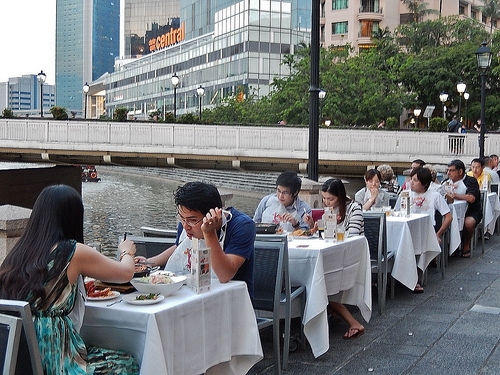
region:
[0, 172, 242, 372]
Man and woman sitting at table eating.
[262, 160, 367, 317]
Man and woman sitting side by side at table.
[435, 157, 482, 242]
Man with napkin under his chin.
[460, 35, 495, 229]
Black ornamental sidewalk light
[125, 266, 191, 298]
White porcelain bowl holding food.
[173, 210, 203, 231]
Eye glasses on man's face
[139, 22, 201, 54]
Large lettered sign on top of building.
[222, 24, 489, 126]
Trees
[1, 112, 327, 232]
Bridge over water.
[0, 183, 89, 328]
Long black hair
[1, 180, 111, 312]
beautiful long straight black hair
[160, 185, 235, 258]
man with brown wire glasses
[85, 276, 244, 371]
clean white linen table cloth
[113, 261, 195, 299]
large dish of white rice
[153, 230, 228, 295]
large white bib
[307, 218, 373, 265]
half mug of beer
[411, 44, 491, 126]
assorted sizes of street lights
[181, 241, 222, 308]
tri page advertisement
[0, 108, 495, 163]
long white walkway across river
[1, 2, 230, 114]
several tall buildings in the city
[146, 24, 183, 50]
Business sign on the side of building.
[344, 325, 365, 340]
Pair of women's dress sandals.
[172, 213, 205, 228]
Clear pair of men's glasses.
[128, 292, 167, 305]
Small side plate on a table.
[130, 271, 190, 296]
Large salad bowl on a table.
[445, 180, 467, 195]
Red and white bib on a man's neck.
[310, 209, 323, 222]
Red menu in woman's hand.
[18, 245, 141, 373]
Woman wearing green and white dress.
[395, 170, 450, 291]
Young Asian man eating outdoors.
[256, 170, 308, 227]
Heavy set Asian man having dinner outdoors.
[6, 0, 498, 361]
outdoor daytime city restaurant scene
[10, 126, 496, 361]
tables with Asian couples eating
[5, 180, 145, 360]
woman in foreground with long black hair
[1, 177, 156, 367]
woman in foreground wearing aqua dress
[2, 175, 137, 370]
woman eating with black chop sticks in foreground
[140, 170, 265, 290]
Asian man in foreground wearing white and red bib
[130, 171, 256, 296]
man in foreground wearing blue shirt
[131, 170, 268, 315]
man in foreground wearing glasses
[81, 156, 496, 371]
tables with white tablecloths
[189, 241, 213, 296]
white open menu on table in foreground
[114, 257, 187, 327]
White dishes on the table.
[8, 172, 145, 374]
Woman eating dinner.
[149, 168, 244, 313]
Man eating at table.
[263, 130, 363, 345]
Two people at a table.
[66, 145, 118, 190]
Water boat on water.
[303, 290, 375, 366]
A foot with a sandal on it.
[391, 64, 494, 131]
A group of whit lights.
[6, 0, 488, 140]
Tall buildings and trees.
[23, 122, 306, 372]
People dining by the water.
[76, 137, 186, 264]
Water with small quakes.